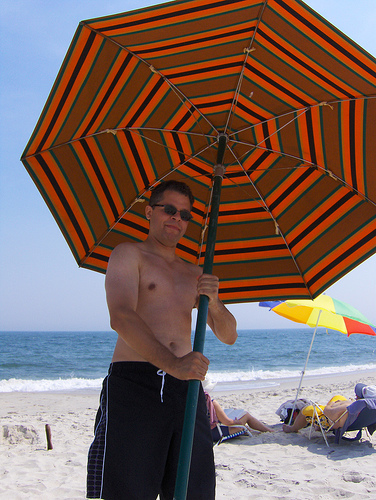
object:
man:
[84, 177, 242, 500]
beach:
[0, 365, 375, 500]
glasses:
[151, 203, 194, 222]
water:
[0, 327, 376, 379]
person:
[282, 381, 376, 435]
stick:
[45, 422, 54, 449]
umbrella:
[18, 0, 376, 306]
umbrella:
[257, 289, 376, 338]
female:
[201, 389, 276, 442]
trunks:
[85, 239, 239, 499]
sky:
[2, 0, 375, 328]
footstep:
[0, 420, 40, 450]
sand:
[0, 369, 376, 499]